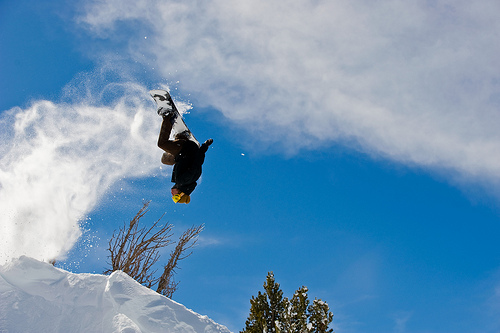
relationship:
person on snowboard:
[152, 93, 214, 204] [147, 87, 200, 148]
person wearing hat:
[152, 93, 214, 204] [177, 194, 190, 204]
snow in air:
[1, 36, 246, 274] [1, 0, 499, 332]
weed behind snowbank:
[157, 224, 207, 300] [0, 255, 234, 333]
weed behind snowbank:
[103, 196, 176, 288] [0, 255, 234, 333]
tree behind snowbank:
[240, 271, 333, 332] [0, 255, 234, 333]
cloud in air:
[67, 1, 500, 202] [1, 0, 499, 332]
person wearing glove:
[152, 93, 214, 204] [204, 138, 214, 147]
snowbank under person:
[0, 255, 234, 333] [152, 93, 214, 204]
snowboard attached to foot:
[147, 87, 200, 148] [157, 107, 179, 120]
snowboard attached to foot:
[147, 87, 200, 148] [174, 129, 195, 140]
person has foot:
[152, 93, 214, 204] [157, 107, 179, 120]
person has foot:
[152, 93, 214, 204] [174, 129, 195, 140]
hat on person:
[177, 194, 190, 204] [152, 93, 214, 204]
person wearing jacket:
[152, 93, 214, 204] [171, 139, 208, 194]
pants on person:
[157, 115, 189, 166] [152, 93, 214, 204]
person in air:
[152, 93, 214, 204] [1, 0, 499, 332]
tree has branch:
[240, 271, 333, 332] [308, 298, 335, 332]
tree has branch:
[240, 271, 333, 332] [290, 286, 310, 333]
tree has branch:
[240, 271, 333, 332] [263, 271, 291, 333]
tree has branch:
[240, 271, 333, 332] [239, 290, 270, 333]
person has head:
[152, 93, 214, 204] [171, 185, 191, 204]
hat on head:
[177, 194, 190, 204] [171, 185, 191, 204]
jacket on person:
[171, 139, 208, 194] [152, 93, 214, 204]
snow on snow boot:
[161, 107, 169, 118] [157, 107, 179, 120]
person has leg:
[152, 93, 214, 204] [157, 115, 186, 155]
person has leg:
[152, 93, 214, 204] [161, 152, 175, 165]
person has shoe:
[152, 93, 214, 204] [157, 106, 177, 119]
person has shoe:
[152, 93, 214, 204] [174, 130, 191, 139]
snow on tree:
[1, 36, 246, 274] [240, 271, 333, 332]